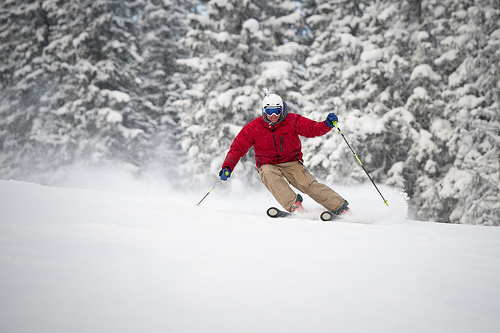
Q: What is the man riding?
A: Skis.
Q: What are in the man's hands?
A: Ski poles.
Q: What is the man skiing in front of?
A: Trees.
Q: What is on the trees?
A: Snow.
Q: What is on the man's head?
A: A helmet.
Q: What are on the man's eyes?
A: Ski goggles.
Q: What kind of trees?
A: Green pine trees.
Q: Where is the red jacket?
A: On the man.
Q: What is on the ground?
A: Snow.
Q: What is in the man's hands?
A: Ski poles.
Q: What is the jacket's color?
A: Red.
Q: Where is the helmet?
A: On the man's head.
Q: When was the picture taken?
A: Daytime.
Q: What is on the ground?
A: Snow.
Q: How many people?
A: 1.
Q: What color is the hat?
A: White.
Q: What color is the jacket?
A: Red.